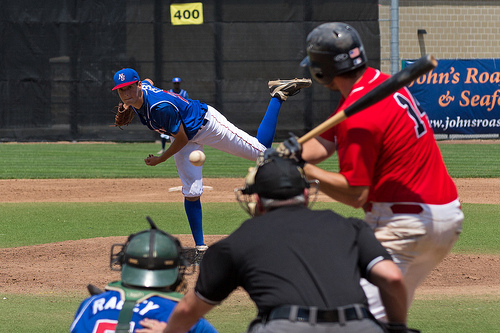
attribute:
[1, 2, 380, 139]
wall — black, mesh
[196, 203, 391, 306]
shirt — black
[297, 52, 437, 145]
bat — baseball bat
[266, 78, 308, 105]
cleat — nike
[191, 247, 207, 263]
cleat — nike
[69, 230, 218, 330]
catcher — set up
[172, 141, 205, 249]
leg — stiff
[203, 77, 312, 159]
leg — stiff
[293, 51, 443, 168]
bat — used in baseball game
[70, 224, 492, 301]
mound — baseball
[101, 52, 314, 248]
pitcher — lanky, left-handed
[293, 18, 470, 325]
batter — red, white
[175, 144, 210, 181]
baseball — white, red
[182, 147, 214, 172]
baseball — white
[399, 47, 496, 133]
banner — blue, orange, white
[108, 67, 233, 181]
pitch — spinning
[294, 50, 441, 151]
bat — black, tan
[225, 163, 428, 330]
man shirt — black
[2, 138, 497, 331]
baseball field — green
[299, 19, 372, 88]
helmet — black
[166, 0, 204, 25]
sign — yellow, number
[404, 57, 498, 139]
sign — number, yellow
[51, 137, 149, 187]
grass — green